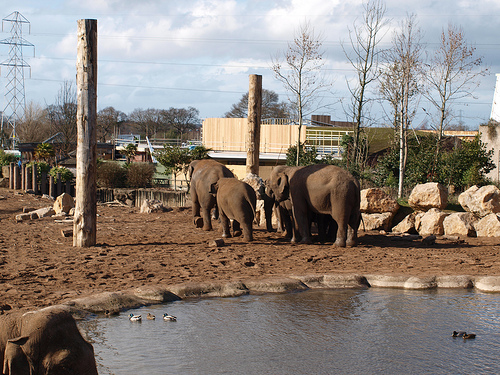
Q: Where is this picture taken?
A: Zoo.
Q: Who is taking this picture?
A: Visitor.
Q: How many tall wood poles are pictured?
A: Two.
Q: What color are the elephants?
A: Brown and gray.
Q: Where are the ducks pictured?
A: In pond.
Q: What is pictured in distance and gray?
A: Power pole.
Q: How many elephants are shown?
A: 5.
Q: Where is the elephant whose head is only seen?
A: In water.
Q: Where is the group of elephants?
A: In the dirt.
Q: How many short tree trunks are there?
A: 2.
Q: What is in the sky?
A: Clouds.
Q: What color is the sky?
A: Grey.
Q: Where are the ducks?
A: In the water.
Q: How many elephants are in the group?
A: 4.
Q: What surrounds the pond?
A: Rock barrier.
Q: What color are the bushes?
A: Green.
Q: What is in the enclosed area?
A: Animals.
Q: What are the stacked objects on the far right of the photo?
A: Stones.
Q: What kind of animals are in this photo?
A: Elephants and ducks.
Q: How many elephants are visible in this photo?
A: Five.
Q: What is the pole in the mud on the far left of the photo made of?
A: Wood.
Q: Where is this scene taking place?
A: Zoo.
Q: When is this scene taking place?
A: Day time.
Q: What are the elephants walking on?
A: Mud.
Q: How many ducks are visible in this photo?
A: Six.